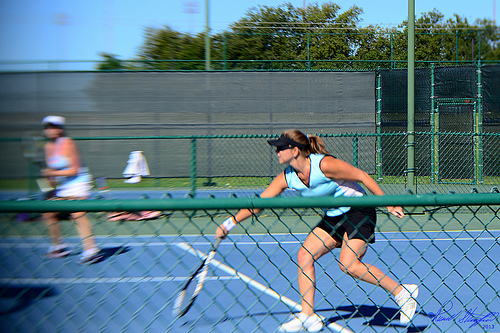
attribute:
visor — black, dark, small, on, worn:
[266, 125, 295, 147]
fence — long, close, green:
[122, 205, 315, 314]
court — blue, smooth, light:
[425, 242, 497, 290]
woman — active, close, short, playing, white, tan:
[211, 131, 421, 332]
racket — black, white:
[174, 233, 231, 319]